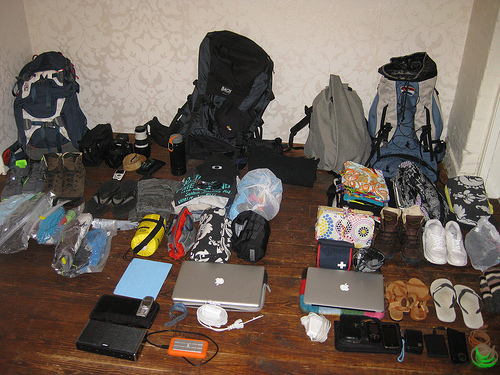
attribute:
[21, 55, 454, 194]
backpacks — Black 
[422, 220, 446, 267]
tennis shoe — White 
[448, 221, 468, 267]
tennis shoe — White 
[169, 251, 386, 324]
two laptops — Gray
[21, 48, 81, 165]
backpack — blue, white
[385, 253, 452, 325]
thongs — someone's, ready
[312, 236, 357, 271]
kit — Blue , Red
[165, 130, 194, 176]
bottle — Closed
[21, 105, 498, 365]
table — Full 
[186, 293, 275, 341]
adaptors — White 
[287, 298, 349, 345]
adaptors — White 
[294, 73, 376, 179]
backpack — Ready 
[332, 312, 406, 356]
electronic devices — black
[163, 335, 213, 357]
cell phone — Orange 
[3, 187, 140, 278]
bags — Black 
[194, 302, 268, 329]
cable — Wound 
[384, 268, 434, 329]
sandals — brown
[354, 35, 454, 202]
backpack — blue , grey 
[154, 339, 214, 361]
device — small, orange, electrical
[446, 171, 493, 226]
towels — Folded 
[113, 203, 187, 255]
travel pack — small, yellow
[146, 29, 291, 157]
bag — silver, blue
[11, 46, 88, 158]
bag — blue, white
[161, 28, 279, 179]
backpack — black, gray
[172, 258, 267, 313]
laptop — Apple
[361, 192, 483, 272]
tennis shoes — plain, white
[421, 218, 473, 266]
tennis shoes — White 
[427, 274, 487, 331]
flip flops — Beige, , zoris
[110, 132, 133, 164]
camera — black, barely perceptible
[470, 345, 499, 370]
green band — Green 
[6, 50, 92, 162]
backpacks — Black , Gray 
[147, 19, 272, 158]
backpacks — Black 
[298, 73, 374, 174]
backpacks — Gray 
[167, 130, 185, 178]
bottle — Cold 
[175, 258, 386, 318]
laptops — Gray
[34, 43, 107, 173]
back pack — Black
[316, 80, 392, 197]
bag — colorful, decorated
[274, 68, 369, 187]
backpack — grey 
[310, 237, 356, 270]
case — Navy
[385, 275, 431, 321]
sandals — Brown 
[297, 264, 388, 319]
laptop computer — small, silver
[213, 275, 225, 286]
apple — logo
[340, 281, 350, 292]
apple — logo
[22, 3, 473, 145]
wall — back